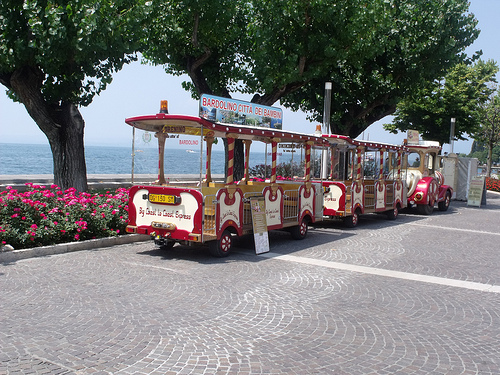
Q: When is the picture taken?
A: During the day.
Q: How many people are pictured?
A: None.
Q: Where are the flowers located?
A: Next to the trolley.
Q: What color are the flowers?
A: Pink.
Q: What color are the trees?
A: Green.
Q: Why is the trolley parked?
A: Because there are no passengers.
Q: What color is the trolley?
A: Red and white.